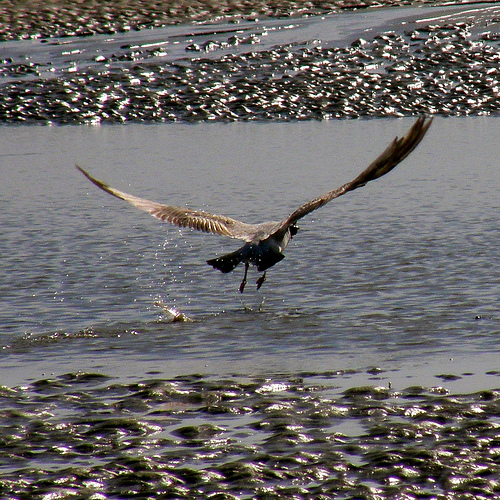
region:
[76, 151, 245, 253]
long outstreched wing of a bird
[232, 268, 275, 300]
feet of a bird in flight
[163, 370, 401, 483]
rocks on the shore line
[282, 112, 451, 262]
big wing of a bird in flight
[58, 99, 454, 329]
bird flying over the water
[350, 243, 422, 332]
calm body of water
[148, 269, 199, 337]
fish flapping in the water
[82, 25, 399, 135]
sunlight off of the rocks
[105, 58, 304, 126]
wet rocks along the shore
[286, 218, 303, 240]
dark head of a flying bird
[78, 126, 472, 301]
Small bird in the water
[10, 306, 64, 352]
Ripples in the water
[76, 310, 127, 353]
Ripples in the water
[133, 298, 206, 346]
Ripples in the water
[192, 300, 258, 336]
Ripples in the water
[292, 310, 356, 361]
Ripples in the water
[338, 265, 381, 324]
Ripples in the water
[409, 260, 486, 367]
Ripples in the water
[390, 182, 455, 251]
Ripples in the water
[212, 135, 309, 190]
Ripples in the water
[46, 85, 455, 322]
The bird is flying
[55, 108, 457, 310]
Wings are spreading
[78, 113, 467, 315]
Bird is low to the ground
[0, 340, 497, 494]
Rocks in the water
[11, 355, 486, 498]
Seaweed is poking out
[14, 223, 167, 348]
Water is calm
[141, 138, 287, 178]
Deep blue water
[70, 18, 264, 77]
Light reflecting in the shot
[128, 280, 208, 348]
Fish in the water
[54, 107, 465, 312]
Bird is brown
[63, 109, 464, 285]
Seagull in flight.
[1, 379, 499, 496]
Sea Weed near the shore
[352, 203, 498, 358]
Water looks murky blue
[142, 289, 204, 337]
Fish that looks to have been dropped by the gull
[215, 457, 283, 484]
Seaweed has a green color to it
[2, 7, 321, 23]
The distance shore is rocky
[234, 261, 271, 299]
The seagull's feet can be seen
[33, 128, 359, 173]
The water is calm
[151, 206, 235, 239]
Seagull wing is partly brown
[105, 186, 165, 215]
The seagull wing is partly white.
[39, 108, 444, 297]
A bird flying just above the water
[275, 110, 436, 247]
the bird's right wing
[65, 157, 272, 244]
the bird's left wing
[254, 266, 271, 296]
the bird's right foot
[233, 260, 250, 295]
the bird's left foot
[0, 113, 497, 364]
Water underneath the bird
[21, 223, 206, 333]
A splash behind the bird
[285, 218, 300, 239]
The bird's head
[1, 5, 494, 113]
Rocks in front of the water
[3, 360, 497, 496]
Rocks behind the bird